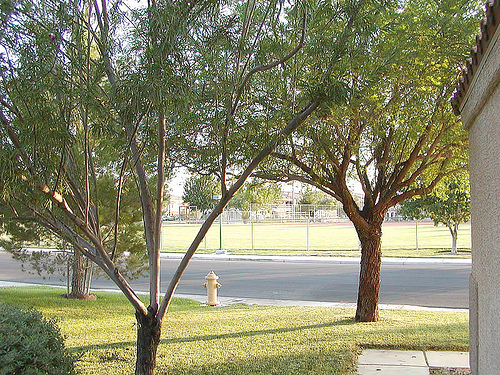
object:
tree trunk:
[134, 312, 167, 375]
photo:
[3, 0, 499, 375]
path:
[348, 347, 473, 375]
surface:
[0, 257, 469, 308]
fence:
[203, 219, 420, 253]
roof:
[440, 0, 499, 116]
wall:
[470, 82, 500, 375]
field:
[0, 203, 500, 375]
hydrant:
[201, 267, 224, 308]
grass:
[0, 281, 474, 375]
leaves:
[23, 59, 44, 75]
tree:
[168, 0, 485, 323]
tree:
[0, 0, 369, 375]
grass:
[148, 210, 476, 261]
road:
[2, 248, 477, 312]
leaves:
[395, 51, 421, 63]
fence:
[219, 211, 349, 225]